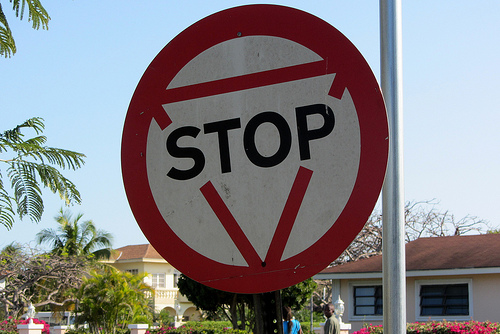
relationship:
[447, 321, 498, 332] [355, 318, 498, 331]
flowers on bush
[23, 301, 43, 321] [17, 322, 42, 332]
statue on stand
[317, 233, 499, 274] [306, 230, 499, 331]
roof on house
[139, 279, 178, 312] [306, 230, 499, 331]
balcony on house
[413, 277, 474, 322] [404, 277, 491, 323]
trim around window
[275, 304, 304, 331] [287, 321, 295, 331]
woman has ponytail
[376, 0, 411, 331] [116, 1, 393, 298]
pole next to sign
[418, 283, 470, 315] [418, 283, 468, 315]
window with slats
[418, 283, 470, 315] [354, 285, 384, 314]
window with slats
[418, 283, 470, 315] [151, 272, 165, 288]
window with slats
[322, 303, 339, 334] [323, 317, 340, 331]
boy wearing top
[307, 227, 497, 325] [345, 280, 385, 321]
home with window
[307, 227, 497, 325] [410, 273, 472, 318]
home with window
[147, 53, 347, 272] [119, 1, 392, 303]
triangle inside circle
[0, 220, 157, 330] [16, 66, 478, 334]
trees along city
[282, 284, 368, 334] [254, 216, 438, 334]
two people are looking at camera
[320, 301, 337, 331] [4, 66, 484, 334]
boy looking at camera